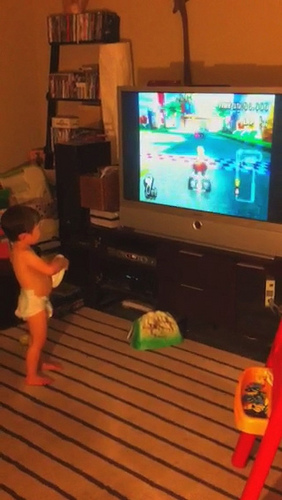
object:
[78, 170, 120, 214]
box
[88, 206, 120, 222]
books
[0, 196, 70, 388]
baby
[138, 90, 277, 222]
screen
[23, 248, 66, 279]
arm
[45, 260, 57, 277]
elbow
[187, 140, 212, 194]
character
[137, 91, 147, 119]
corner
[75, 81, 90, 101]
items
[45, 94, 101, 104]
shelf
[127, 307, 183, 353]
item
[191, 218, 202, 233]
object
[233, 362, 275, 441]
tray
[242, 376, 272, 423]
toys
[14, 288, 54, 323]
diaper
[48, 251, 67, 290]
wheel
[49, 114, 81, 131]
movies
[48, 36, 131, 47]
shelf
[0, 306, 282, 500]
carpet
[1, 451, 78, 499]
sripe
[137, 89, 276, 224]
game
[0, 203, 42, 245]
hair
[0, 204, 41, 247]
head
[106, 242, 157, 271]
electronic device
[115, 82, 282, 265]
television